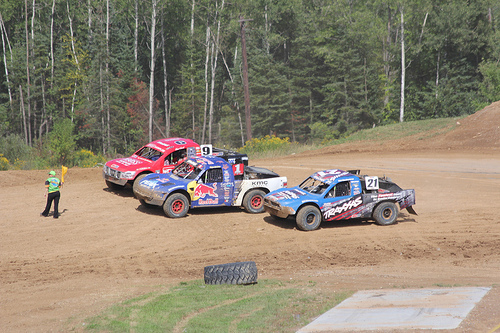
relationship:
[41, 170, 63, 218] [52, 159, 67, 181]
man on flag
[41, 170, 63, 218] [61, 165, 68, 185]
man holding a yellow flag flag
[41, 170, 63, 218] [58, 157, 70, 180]
man with flag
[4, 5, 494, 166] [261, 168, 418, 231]
trees behind car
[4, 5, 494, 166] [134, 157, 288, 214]
trees behind truck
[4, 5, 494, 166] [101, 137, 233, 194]
trees behind car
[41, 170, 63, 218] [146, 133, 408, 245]
man in front of trucks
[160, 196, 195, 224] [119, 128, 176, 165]
rims on truck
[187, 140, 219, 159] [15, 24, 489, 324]
numbers on background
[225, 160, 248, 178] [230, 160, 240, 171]
number on background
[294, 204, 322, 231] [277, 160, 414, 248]
front wheel of truck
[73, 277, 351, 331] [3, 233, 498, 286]
green grass on side of track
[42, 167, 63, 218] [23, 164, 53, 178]
man wearing cap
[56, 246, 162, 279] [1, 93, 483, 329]
lines in dirt